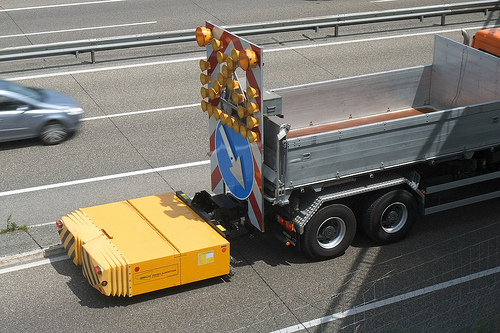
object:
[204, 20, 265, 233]
lights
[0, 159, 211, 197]
line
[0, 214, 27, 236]
grass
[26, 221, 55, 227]
line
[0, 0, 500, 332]
road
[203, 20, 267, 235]
sign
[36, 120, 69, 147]
tire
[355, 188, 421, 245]
back tire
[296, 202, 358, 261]
back tire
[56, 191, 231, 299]
electronic sign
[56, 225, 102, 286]
stripes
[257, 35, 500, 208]
bed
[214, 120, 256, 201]
circle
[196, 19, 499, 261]
truck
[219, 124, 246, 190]
arrow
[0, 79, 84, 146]
car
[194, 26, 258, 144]
light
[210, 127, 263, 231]
stripes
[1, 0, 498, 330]
ground